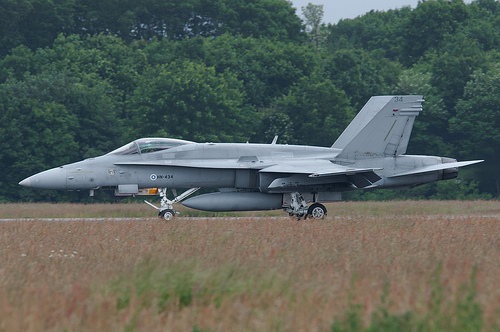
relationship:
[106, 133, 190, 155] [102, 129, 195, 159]
enclosure over cockpit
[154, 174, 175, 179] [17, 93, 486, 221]
numbering on side of airplane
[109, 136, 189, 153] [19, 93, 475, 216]
cockpit of airplane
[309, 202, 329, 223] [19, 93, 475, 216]
wheel on airplane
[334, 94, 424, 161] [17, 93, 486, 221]
vertical stabalizer on back of airplane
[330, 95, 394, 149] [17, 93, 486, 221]
vertical stabalizer on back of airplane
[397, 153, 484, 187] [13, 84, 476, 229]
propeller on back of airplane